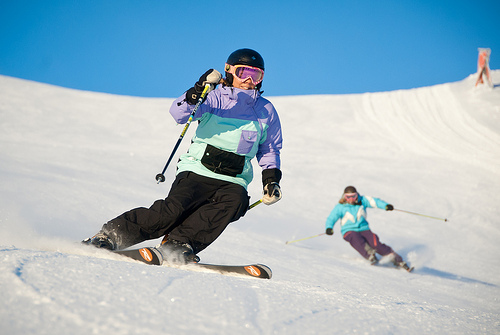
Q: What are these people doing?
A: Skiing.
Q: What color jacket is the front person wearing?
A: Purple.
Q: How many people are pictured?
A: 2.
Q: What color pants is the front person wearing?
A: Black.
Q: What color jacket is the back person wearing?
A: Blue.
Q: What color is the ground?
A: White.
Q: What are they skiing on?
A: Snow.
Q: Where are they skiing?
A: A mountain.